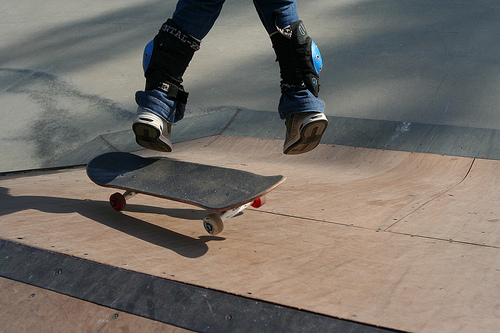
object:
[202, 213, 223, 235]
wheel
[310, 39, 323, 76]
blue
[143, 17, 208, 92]
pad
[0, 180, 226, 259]
shadow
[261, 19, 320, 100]
pad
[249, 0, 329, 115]
leg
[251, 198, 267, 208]
wheel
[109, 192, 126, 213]
wheel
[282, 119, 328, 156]
shoe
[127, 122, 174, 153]
shoe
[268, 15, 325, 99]
shin guard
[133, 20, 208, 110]
shin guard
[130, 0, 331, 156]
person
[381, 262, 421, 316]
black mark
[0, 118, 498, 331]
ramp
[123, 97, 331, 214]
air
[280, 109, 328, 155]
feet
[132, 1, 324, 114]
jeans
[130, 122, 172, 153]
soles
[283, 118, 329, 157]
soles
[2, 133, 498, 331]
ground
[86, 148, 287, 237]
skateboard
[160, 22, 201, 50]
letters